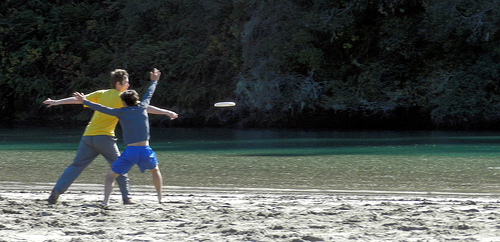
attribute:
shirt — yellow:
[79, 89, 129, 136]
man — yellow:
[52, 70, 104, 196]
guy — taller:
[42, 67, 176, 204]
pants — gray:
[50, 114, 130, 196]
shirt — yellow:
[82, 90, 124, 137]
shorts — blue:
[99, 137, 164, 176]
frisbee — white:
[216, 96, 237, 112]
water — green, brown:
[3, 123, 498, 196]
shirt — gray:
[78, 95, 188, 158]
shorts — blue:
[105, 142, 164, 177]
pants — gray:
[54, 137, 117, 194]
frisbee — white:
[214, 100, 235, 107]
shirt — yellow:
[88, 91, 128, 132]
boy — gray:
[40, 75, 210, 205]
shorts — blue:
[114, 137, 163, 179]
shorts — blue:
[111, 149, 158, 176]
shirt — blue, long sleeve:
[113, 102, 156, 143]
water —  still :
[0, 135, 496, 192]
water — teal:
[239, 130, 499, 176]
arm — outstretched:
[128, 61, 177, 133]